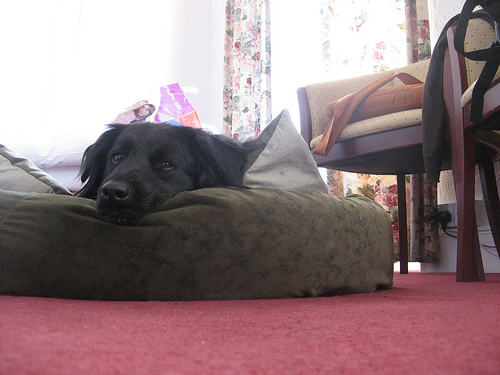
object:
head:
[95, 122, 199, 220]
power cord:
[435, 201, 497, 251]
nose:
[101, 179, 130, 199]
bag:
[113, 82, 199, 126]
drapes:
[223, 1, 443, 264]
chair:
[298, 6, 500, 282]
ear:
[74, 122, 123, 199]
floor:
[1, 271, 500, 372]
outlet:
[435, 203, 457, 227]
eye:
[158, 159, 173, 171]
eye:
[113, 151, 125, 161]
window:
[271, 0, 405, 197]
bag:
[312, 71, 424, 158]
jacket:
[420, 0, 496, 183]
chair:
[442, 11, 496, 281]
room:
[0, 0, 499, 374]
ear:
[206, 132, 247, 186]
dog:
[75, 122, 258, 219]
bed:
[0, 186, 395, 300]